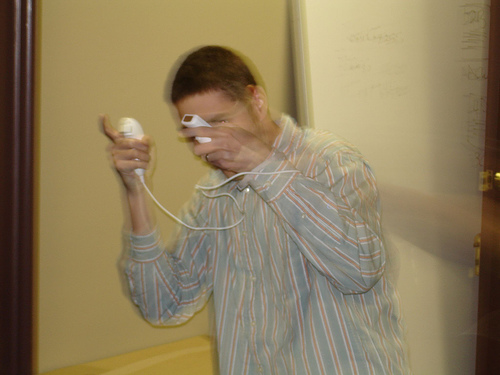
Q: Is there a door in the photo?
A: Yes, there is a door.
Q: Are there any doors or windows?
A: Yes, there is a door.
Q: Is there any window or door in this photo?
A: Yes, there is a door.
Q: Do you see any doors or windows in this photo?
A: Yes, there is a door.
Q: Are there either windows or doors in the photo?
A: Yes, there is a door.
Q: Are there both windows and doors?
A: No, there is a door but no windows.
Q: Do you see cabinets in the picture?
A: No, there are no cabinets.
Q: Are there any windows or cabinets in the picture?
A: No, there are no cabinets or windows.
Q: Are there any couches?
A: Yes, there is a couch.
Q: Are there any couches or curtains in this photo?
A: Yes, there is a couch.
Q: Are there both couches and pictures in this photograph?
A: No, there is a couch but no pictures.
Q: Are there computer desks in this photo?
A: No, there are no computer desks.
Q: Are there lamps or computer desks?
A: No, there are no computer desks or lamps.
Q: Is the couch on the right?
A: No, the couch is on the left of the image.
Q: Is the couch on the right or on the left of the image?
A: The couch is on the left of the image.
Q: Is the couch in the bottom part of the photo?
A: Yes, the couch is in the bottom of the image.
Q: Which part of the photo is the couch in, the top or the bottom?
A: The couch is in the bottom of the image.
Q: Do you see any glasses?
A: No, there are no glasses.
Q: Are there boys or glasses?
A: No, there are no glasses or boys.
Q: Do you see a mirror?
A: No, there are no mirrors.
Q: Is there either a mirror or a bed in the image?
A: No, there are no mirrors or beds.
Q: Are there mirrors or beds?
A: No, there are no mirrors or beds.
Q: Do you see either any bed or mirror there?
A: No, there are no mirrors or beds.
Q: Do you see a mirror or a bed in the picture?
A: No, there are no mirrors or beds.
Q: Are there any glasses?
A: No, there are no glasses.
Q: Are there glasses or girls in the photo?
A: No, there are no glasses or girls.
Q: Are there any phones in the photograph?
A: No, there are no phones.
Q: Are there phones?
A: No, there are no phones.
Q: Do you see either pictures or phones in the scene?
A: No, there are no phones or pictures.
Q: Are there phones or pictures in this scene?
A: No, there are no phones or pictures.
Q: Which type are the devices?
A: The devices are controllers.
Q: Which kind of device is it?
A: The devices are controllers.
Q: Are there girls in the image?
A: No, there are no girls.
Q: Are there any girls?
A: No, there are no girls.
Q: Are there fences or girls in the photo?
A: No, there are no girls or fences.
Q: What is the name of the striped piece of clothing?
A: The clothing item is a shirt.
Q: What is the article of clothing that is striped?
A: The clothing item is a shirt.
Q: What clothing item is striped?
A: The clothing item is a shirt.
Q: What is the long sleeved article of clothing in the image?
A: The clothing item is a shirt.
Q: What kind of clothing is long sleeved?
A: The clothing is a shirt.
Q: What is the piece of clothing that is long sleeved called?
A: The clothing item is a shirt.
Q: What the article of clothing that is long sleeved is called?
A: The clothing item is a shirt.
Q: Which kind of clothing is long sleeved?
A: The clothing is a shirt.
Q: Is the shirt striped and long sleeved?
A: Yes, the shirt is striped and long sleeved.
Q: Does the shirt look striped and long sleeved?
A: Yes, the shirt is striped and long sleeved.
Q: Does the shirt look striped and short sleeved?
A: No, the shirt is striped but long sleeved.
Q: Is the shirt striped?
A: Yes, the shirt is striped.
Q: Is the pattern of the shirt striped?
A: Yes, the shirt is striped.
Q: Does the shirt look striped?
A: Yes, the shirt is striped.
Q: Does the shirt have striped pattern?
A: Yes, the shirt is striped.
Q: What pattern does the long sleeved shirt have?
A: The shirt has striped pattern.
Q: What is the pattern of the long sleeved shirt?
A: The shirt is striped.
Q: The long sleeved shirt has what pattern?
A: The shirt is striped.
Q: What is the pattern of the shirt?
A: The shirt is striped.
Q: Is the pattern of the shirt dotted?
A: No, the shirt is striped.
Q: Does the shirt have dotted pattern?
A: No, the shirt is striped.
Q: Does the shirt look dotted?
A: No, the shirt is striped.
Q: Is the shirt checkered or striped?
A: The shirt is striped.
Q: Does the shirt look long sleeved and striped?
A: Yes, the shirt is long sleeved and striped.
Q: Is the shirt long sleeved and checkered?
A: No, the shirt is long sleeved but striped.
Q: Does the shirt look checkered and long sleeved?
A: No, the shirt is long sleeved but striped.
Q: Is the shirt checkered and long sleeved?
A: No, the shirt is long sleeved but striped.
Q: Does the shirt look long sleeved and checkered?
A: No, the shirt is long sleeved but striped.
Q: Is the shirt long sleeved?
A: Yes, the shirt is long sleeved.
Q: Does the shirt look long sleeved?
A: Yes, the shirt is long sleeved.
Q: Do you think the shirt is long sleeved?
A: Yes, the shirt is long sleeved.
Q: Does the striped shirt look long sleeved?
A: Yes, the shirt is long sleeved.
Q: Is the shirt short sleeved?
A: No, the shirt is long sleeved.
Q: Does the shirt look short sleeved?
A: No, the shirt is long sleeved.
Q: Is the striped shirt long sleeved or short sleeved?
A: The shirt is long sleeved.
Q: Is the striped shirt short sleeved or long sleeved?
A: The shirt is long sleeved.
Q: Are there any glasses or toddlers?
A: No, there are no glasses or toddlers.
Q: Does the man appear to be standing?
A: Yes, the man is standing.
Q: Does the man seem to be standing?
A: Yes, the man is standing.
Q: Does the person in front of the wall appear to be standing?
A: Yes, the man is standing.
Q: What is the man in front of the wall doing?
A: The man is standing.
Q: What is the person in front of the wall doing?
A: The man is standing.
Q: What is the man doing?
A: The man is standing.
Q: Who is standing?
A: The man is standing.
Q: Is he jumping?
A: No, the man is standing.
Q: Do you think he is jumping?
A: No, the man is standing.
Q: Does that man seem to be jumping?
A: No, the man is standing.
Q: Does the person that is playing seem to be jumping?
A: No, the man is standing.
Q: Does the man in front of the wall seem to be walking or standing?
A: The man is standing.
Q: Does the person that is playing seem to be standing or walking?
A: The man is standing.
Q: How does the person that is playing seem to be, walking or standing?
A: The man is standing.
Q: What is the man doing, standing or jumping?
A: The man is standing.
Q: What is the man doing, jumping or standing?
A: The man is standing.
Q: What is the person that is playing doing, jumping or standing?
A: The man is standing.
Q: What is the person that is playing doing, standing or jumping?
A: The man is standing.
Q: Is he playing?
A: Yes, the man is playing.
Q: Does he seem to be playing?
A: Yes, the man is playing.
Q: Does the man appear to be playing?
A: Yes, the man is playing.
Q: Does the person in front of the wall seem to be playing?
A: Yes, the man is playing.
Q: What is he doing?
A: The man is playing.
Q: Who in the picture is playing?
A: The man is playing.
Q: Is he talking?
A: No, the man is playing.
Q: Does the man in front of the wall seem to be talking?
A: No, the man is playing.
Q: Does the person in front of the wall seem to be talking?
A: No, the man is playing.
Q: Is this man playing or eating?
A: The man is playing.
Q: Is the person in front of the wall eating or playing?
A: The man is playing.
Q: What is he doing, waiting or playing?
A: The man is playing.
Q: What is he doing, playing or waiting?
A: The man is playing.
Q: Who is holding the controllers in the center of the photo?
A: The man is holding the controllers.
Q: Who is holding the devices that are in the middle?
A: The man is holding the controllers.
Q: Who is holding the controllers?
A: The man is holding the controllers.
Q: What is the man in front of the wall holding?
A: The man is holding the controllers.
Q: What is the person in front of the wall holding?
A: The man is holding the controllers.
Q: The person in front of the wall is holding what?
A: The man is holding the controllers.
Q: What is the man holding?
A: The man is holding the controllers.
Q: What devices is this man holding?
A: The man is holding the controllers.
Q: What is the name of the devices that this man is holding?
A: The devices are controllers.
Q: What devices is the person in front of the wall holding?
A: The man is holding the controllers.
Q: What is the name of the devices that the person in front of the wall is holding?
A: The devices are controllers.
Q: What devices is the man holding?
A: The man is holding the controllers.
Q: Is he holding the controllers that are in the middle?
A: Yes, the man is holding the controllers.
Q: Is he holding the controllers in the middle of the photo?
A: Yes, the man is holding the controllers.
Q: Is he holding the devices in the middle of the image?
A: Yes, the man is holding the controllers.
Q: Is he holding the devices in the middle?
A: Yes, the man is holding the controllers.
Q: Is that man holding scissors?
A: No, the man is holding the controllers.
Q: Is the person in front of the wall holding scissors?
A: No, the man is holding the controllers.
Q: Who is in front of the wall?
A: The man is in front of the wall.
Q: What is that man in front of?
A: The man is in front of the wall.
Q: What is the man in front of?
A: The man is in front of the wall.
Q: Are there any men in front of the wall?
A: Yes, there is a man in front of the wall.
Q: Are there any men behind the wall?
A: No, the man is in front of the wall.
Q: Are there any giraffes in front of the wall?
A: No, there is a man in front of the wall.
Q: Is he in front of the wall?
A: Yes, the man is in front of the wall.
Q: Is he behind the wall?
A: No, the man is in front of the wall.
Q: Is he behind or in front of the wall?
A: The man is in front of the wall.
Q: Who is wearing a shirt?
A: The man is wearing a shirt.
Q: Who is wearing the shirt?
A: The man is wearing a shirt.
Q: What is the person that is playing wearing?
A: The man is wearing a shirt.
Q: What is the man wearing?
A: The man is wearing a shirt.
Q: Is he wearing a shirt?
A: Yes, the man is wearing a shirt.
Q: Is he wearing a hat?
A: No, the man is wearing a shirt.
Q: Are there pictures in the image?
A: No, there are no pictures.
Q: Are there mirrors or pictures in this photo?
A: No, there are no pictures or mirrors.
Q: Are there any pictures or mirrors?
A: No, there are no pictures or mirrors.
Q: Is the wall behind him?
A: Yes, the wall is behind the man.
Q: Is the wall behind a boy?
A: No, the wall is behind the man.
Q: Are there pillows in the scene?
A: No, there are no pillows.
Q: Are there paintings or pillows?
A: No, there are no pillows or paintings.